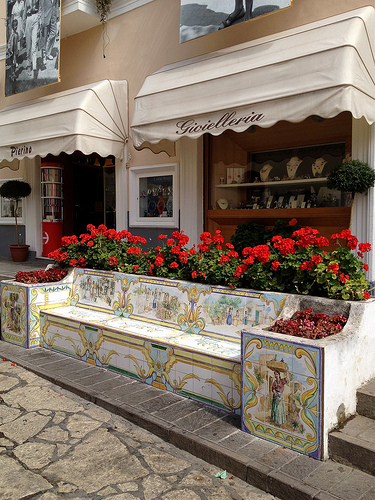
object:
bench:
[0, 266, 373, 462]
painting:
[240, 333, 324, 463]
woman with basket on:
[266, 358, 289, 427]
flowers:
[362, 289, 371, 301]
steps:
[327, 411, 374, 479]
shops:
[0, 0, 127, 267]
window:
[203, 111, 352, 253]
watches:
[267, 196, 272, 209]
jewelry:
[218, 197, 228, 206]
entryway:
[58, 166, 115, 242]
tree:
[0, 178, 32, 246]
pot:
[7, 244, 30, 263]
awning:
[130, 4, 375, 157]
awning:
[0, 77, 129, 172]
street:
[0, 355, 279, 499]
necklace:
[287, 159, 300, 172]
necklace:
[312, 160, 326, 173]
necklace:
[261, 165, 271, 173]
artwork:
[3, 0, 63, 101]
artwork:
[178, 0, 291, 42]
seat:
[39, 303, 241, 362]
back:
[71, 268, 288, 347]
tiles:
[292, 342, 325, 380]